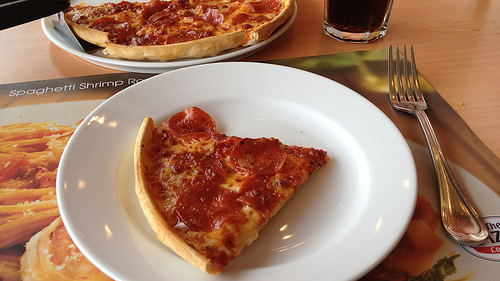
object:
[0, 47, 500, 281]
mat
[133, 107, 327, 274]
pizza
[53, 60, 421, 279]
plate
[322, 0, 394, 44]
glass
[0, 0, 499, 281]
table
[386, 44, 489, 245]
fork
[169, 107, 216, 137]
pepperoni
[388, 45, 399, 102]
tine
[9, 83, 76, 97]
word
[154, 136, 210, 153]
cheese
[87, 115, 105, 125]
light